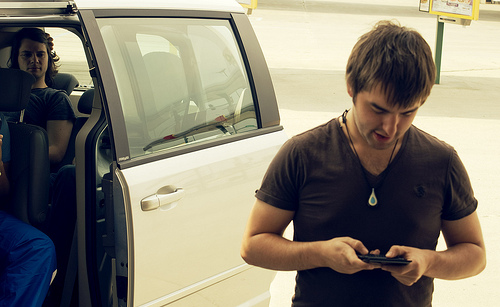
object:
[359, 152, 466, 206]
person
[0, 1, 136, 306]
door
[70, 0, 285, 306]
door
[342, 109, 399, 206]
necklace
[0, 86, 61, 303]
person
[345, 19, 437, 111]
hair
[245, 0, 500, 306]
ground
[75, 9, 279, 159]
window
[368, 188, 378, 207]
pendant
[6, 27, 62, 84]
hair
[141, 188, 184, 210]
handle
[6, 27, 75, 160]
guy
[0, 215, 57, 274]
knee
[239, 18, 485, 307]
guy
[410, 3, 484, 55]
objects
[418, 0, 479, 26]
object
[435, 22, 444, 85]
pole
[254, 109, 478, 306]
shirt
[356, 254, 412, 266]
cell phone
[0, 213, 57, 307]
leg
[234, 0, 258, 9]
object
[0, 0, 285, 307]
car